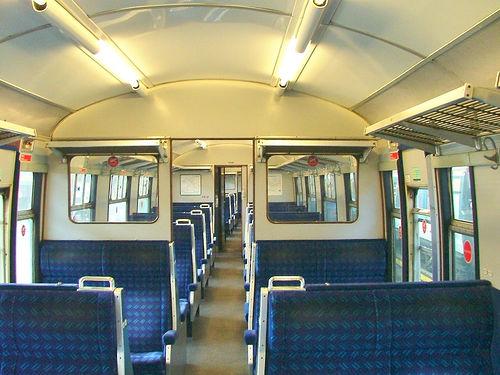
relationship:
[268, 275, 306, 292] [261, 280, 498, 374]
handle on bench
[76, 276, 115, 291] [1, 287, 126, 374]
handle bar on bench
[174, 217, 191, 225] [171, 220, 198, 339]
handle bar on bench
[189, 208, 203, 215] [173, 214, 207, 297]
handle bar on bench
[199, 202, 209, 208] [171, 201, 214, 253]
handle bar on bench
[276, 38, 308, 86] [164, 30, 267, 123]
light on ceiling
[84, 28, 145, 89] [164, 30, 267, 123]
light on ceiling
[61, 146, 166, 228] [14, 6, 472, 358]
window on train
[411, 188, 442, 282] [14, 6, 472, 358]
window on train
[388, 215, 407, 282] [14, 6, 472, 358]
window on train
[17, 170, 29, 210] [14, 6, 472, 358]
window on train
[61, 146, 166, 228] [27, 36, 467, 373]
window on train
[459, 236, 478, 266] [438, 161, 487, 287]
red sticker on window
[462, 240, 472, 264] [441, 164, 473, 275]
red sticker on window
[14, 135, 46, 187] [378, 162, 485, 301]
sticker on window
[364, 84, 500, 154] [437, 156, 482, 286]
rack above window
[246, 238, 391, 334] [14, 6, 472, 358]
seat on train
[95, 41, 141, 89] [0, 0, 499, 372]
light on passenger wagon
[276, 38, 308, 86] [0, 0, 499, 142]
light on ceiling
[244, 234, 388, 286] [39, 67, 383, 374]
seat on train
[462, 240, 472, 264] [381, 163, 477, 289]
red sticker on window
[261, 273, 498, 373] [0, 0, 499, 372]
bench on passenger wagon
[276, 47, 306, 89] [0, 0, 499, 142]
light on ceiling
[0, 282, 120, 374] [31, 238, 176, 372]
blue fabric on bench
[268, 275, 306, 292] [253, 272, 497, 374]
handle on bench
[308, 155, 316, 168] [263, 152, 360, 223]
sticker on window